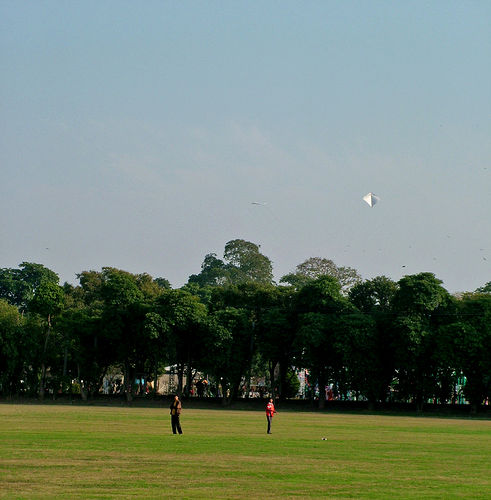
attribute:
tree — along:
[48, 275, 142, 402]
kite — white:
[362, 193, 380, 206]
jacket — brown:
[167, 395, 181, 417]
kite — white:
[361, 187, 384, 210]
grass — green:
[2, 401, 489, 498]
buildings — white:
[143, 362, 207, 392]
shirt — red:
[264, 404, 279, 420]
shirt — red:
[266, 400, 275, 416]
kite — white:
[348, 163, 384, 251]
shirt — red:
[265, 404, 272, 418]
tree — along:
[367, 269, 454, 407]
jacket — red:
[246, 401, 299, 441]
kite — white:
[359, 189, 377, 208]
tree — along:
[342, 265, 411, 410]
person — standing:
[265, 395, 276, 434]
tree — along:
[248, 268, 378, 342]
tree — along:
[288, 270, 373, 423]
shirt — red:
[265, 402, 274, 415]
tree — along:
[20, 261, 68, 399]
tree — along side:
[0, 297, 62, 395]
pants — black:
[166, 413, 190, 434]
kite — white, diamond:
[363, 188, 378, 208]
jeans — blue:
[267, 411, 275, 435]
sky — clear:
[0, 3, 488, 294]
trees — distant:
[4, 235, 489, 411]